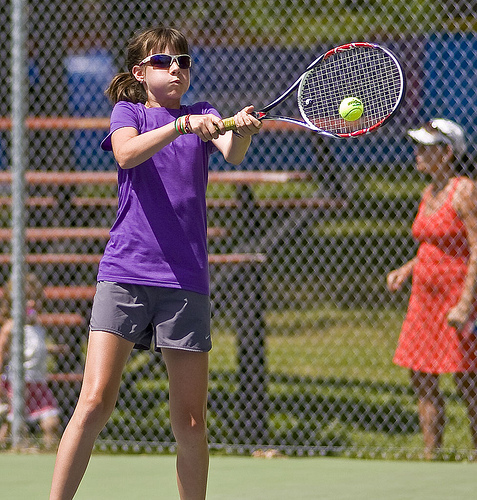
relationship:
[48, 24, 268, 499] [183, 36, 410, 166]
girl swinging a racket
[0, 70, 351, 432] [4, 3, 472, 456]
bleachers behind fence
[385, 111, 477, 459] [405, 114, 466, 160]
woman wearing cap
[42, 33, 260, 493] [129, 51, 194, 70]
girl wearing sunglasses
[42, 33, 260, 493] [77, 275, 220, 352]
girl wearing shorts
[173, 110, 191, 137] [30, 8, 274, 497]
hair bands on wrist of little girl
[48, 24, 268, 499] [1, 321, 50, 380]
girl walking in shirt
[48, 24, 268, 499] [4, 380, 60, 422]
girl walking in shorts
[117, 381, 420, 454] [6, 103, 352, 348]
shadows cast by bleachers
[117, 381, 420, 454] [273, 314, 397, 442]
shadows on grass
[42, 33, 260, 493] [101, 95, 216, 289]
girl wearing shirt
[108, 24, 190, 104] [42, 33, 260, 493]
brown hair of girl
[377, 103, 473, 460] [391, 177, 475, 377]
woman wearing sundress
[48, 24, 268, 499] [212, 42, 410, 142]
girl swinging racket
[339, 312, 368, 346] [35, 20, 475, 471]
grass behind fence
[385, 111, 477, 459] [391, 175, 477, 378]
woman wearing sundress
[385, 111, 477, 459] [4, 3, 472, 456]
woman behind fence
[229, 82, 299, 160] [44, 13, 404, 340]
hand of girl